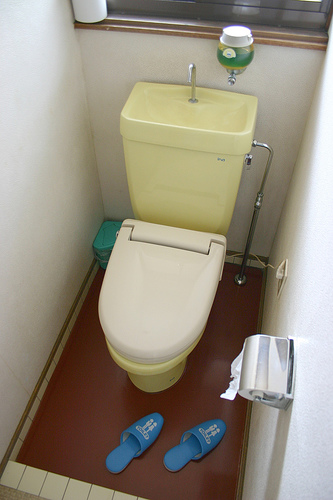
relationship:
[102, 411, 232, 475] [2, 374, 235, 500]
slippers on floor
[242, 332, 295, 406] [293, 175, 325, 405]
holder on wall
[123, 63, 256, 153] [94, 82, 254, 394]
sink on top toilet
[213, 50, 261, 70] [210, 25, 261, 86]
soap in dispenser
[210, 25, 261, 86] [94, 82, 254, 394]
dispenser over toilet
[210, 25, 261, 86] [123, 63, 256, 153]
dispenser over sink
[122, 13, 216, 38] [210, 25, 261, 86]
windowsill above dispenser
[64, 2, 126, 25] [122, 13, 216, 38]
paper on windowsill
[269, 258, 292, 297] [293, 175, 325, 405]
outlet on wall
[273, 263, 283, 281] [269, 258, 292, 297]
plug in outlet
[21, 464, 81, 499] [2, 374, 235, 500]
tiles on floor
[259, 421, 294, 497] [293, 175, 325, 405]
shadow on wall